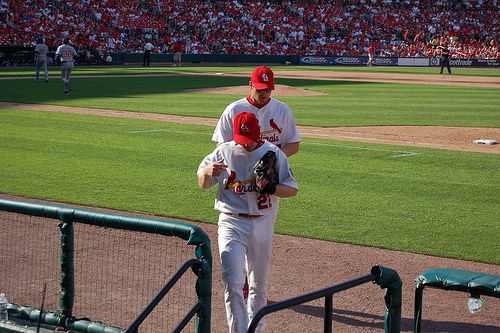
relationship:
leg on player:
[214, 240, 253, 331] [178, 111, 296, 331]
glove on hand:
[251, 150, 280, 196] [249, 171, 278, 194]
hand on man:
[249, 171, 278, 194] [194, 111, 300, 332]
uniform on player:
[191, 144, 298, 330] [180, 109, 323, 330]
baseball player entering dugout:
[197, 111, 297, 330] [6, 192, 498, 329]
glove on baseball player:
[251, 151, 278, 196] [197, 111, 297, 330]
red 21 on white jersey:
[252, 187, 274, 212] [192, 140, 303, 215]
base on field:
[337, 119, 499, 158] [1, 59, 493, 330]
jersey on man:
[196, 139, 300, 217] [231, 63, 306, 141]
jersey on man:
[196, 139, 300, 216] [195, 108, 297, 330]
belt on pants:
[237, 211, 266, 220] [215, 206, 276, 331]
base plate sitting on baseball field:
[474, 138, 497, 147] [0, 63, 497, 258]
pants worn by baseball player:
[215, 209, 276, 331] [197, 111, 297, 330]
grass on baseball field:
[7, 107, 187, 211] [8, 64, 498, 331]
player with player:
[54, 36, 82, 93] [31, 31, 56, 89]